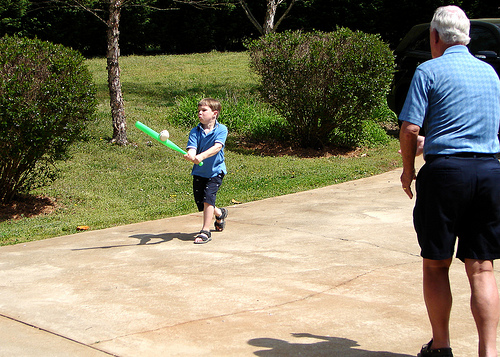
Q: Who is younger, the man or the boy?
A: The boy is younger than the man.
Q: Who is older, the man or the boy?
A: The man is older than the boy.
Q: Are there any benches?
A: No, there are no benches.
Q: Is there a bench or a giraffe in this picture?
A: No, there are no benches or giraffes.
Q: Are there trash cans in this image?
A: No, there are no trash cans.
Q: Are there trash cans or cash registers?
A: No, there are no trash cans or cash registers.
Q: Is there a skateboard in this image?
A: No, there are no skateboards.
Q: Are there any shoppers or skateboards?
A: No, there are no skateboards or shoppers.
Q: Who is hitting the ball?
A: The boy is hitting the ball.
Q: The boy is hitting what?
A: The boy is hitting the ball.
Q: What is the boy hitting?
A: The boy is hitting the ball.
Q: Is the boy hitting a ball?
A: Yes, the boy is hitting a ball.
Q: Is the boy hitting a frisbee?
A: No, the boy is hitting a ball.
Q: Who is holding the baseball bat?
A: The boy is holding the baseball bat.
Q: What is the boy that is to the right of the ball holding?
A: The boy is holding the baseball bat.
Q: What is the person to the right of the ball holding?
A: The boy is holding the baseball bat.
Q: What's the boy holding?
A: The boy is holding the baseball bat.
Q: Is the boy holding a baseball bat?
A: Yes, the boy is holding a baseball bat.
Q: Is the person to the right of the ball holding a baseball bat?
A: Yes, the boy is holding a baseball bat.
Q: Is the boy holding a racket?
A: No, the boy is holding a baseball bat.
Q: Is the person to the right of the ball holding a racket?
A: No, the boy is holding a baseball bat.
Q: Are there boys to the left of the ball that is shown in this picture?
A: No, the boy is to the right of the ball.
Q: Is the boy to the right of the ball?
A: Yes, the boy is to the right of the ball.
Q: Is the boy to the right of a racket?
A: No, the boy is to the right of the ball.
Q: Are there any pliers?
A: No, there are no pliers.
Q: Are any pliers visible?
A: No, there are no pliers.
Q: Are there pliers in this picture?
A: No, there are no pliers.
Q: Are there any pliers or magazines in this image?
A: No, there are no pliers or magazines.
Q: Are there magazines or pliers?
A: No, there are no pliers or magazines.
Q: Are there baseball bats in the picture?
A: Yes, there is a baseball bat.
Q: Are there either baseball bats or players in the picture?
A: Yes, there is a baseball bat.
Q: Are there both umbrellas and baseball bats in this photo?
A: No, there is a baseball bat but no umbrellas.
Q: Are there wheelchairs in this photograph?
A: No, there are no wheelchairs.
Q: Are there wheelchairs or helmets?
A: No, there are no wheelchairs or helmets.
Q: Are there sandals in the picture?
A: Yes, there are sandals.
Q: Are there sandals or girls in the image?
A: Yes, there are sandals.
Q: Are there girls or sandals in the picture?
A: Yes, there are sandals.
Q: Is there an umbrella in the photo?
A: No, there are no umbrellas.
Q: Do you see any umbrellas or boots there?
A: No, there are no umbrellas or boots.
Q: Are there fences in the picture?
A: No, there are no fences.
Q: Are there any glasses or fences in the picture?
A: No, there are no fences or glasses.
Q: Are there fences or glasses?
A: No, there are no fences or glasses.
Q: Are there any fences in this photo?
A: No, there are no fences.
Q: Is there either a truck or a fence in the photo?
A: No, there are no fences or trucks.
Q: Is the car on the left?
A: No, the car is on the right of the image.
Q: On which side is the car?
A: The car is on the right of the image.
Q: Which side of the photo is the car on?
A: The car is on the right of the image.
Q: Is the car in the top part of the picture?
A: Yes, the car is in the top of the image.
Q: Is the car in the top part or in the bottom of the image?
A: The car is in the top of the image.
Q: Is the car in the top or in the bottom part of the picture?
A: The car is in the top of the image.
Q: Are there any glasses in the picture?
A: No, there are no glasses.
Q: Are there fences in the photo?
A: No, there are no fences.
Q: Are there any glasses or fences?
A: No, there are no fences or glasses.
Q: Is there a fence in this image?
A: No, there are no fences.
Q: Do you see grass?
A: Yes, there is grass.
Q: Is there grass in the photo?
A: Yes, there is grass.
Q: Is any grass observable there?
A: Yes, there is grass.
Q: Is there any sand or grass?
A: Yes, there is grass.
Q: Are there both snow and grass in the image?
A: No, there is grass but no snow.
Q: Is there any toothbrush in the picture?
A: No, there are no toothbrushes.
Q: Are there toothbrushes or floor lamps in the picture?
A: No, there are no toothbrushes or floor lamps.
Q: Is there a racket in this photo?
A: No, there are no rackets.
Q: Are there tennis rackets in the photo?
A: No, there are no tennis rackets.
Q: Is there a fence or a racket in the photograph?
A: No, there are no rackets or fences.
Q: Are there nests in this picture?
A: No, there are no nests.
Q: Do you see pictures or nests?
A: No, there are no nests or pictures.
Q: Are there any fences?
A: No, there are no fences.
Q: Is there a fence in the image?
A: No, there are no fences.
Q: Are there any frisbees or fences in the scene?
A: No, there are no fences or frisbees.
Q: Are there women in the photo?
A: No, there are no women.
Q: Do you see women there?
A: No, there are no women.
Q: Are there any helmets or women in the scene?
A: No, there are no women or helmets.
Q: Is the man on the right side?
A: Yes, the man is on the right of the image.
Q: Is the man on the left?
A: No, the man is on the right of the image.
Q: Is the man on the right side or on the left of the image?
A: The man is on the right of the image.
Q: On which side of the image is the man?
A: The man is on the right of the image.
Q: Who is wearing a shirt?
A: The man is wearing a shirt.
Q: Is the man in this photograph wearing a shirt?
A: Yes, the man is wearing a shirt.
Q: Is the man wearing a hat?
A: No, the man is wearing a shirt.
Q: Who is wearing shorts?
A: The man is wearing shorts.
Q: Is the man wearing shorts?
A: Yes, the man is wearing shorts.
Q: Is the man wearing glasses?
A: No, the man is wearing shorts.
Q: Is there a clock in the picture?
A: No, there are no clocks.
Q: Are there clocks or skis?
A: No, there are no clocks or skis.